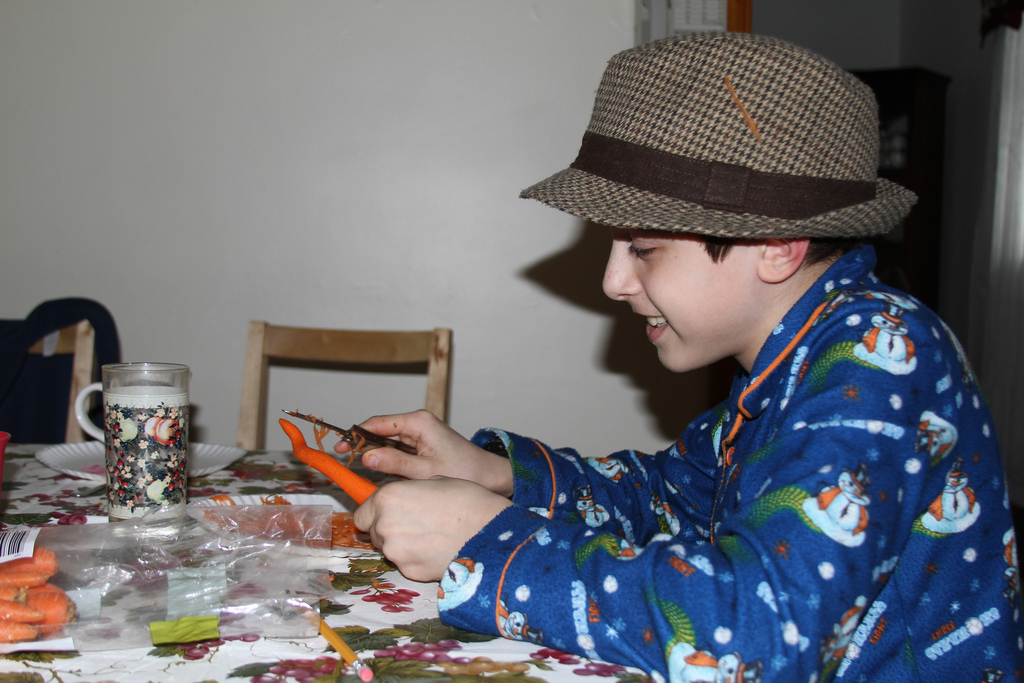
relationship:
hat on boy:
[514, 35, 925, 249] [338, 28, 1022, 682]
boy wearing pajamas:
[338, 28, 1022, 682] [638, 498, 822, 602]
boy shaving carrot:
[338, 28, 1022, 682] [223, 335, 504, 567]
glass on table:
[87, 366, 228, 514] [204, 618, 349, 677]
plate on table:
[44, 437, 138, 528] [182, 521, 314, 653]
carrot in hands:
[278, 385, 371, 494] [349, 364, 443, 572]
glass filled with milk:
[100, 361, 194, 539] [107, 366, 138, 416]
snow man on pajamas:
[809, 452, 881, 563] [434, 260, 1024, 682]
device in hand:
[241, 349, 401, 488] [334, 364, 471, 509]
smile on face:
[636, 299, 699, 358] [597, 217, 736, 388]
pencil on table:
[299, 584, 351, 678] [312, 588, 425, 671]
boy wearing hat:
[338, 28, 1022, 682] [530, 27, 870, 237]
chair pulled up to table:
[249, 344, 425, 425] [232, 450, 326, 544]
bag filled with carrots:
[7, 530, 109, 673] [12, 519, 99, 651]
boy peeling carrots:
[543, 201, 913, 660] [239, 361, 440, 530]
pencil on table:
[299, 584, 377, 682] [139, 584, 282, 675]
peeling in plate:
[250, 493, 352, 578] [202, 486, 369, 605]